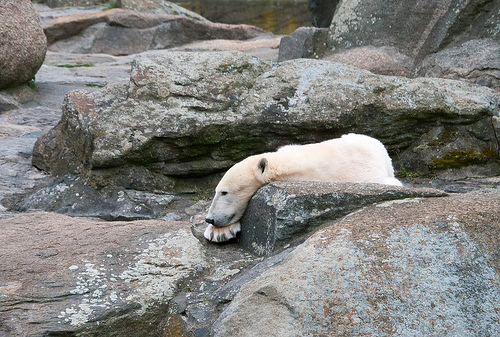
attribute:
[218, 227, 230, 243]
claw — black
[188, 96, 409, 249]
polar bear — white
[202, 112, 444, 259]
bear — polar, white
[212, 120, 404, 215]
bear — white, polar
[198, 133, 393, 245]
bear — white, furry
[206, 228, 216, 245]
claw — black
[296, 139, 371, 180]
loin — white, furry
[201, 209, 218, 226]
nose — little, black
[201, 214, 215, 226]
nose — black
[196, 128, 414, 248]
polar bear — white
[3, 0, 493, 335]
rocks — big, moldy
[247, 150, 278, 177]
ear — black, furry, little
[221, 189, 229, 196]
eye — polar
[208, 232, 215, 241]
claw — black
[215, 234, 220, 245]
claw — black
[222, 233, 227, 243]
claw — black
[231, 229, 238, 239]
claw — black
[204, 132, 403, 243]
polar bear — white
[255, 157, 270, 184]
ear — large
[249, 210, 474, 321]
stone — gray, brown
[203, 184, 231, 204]
eyes — dark, black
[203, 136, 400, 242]
bear — big, white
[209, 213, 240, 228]
mouth — black